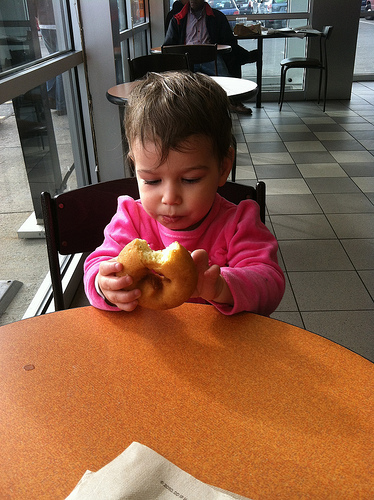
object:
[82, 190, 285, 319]
sweater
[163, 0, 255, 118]
man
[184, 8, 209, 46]
shirt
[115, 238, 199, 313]
donut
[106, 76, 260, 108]
empty table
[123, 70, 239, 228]
head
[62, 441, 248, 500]
napkin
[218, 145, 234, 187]
ear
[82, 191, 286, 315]
shirt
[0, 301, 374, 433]
table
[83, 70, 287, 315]
baby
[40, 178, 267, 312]
chair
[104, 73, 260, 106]
table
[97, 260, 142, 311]
hand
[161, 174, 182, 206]
nose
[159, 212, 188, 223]
mouth